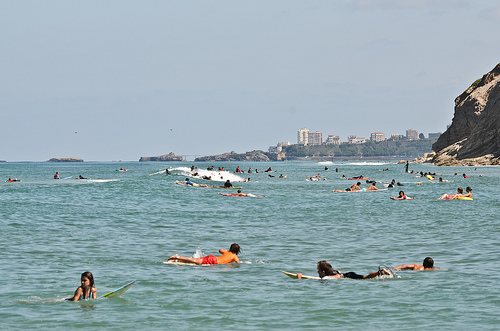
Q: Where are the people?
A: In the ocean.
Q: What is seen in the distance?
A: Buildings.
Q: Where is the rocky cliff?
A: On the right side of the picture.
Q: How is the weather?
A: Warm and clear.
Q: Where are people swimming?
A: On the beach.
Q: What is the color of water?
A: Blue.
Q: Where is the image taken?
A: In water.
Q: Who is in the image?
A: People.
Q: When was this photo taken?
A: Daytime.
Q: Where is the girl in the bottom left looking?
A: Off to the left.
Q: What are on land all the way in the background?
A: Buildings.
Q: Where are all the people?
A: In the water.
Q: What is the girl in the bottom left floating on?
A: Surf board.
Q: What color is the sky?
A: Pale blue.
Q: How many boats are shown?
A: None.